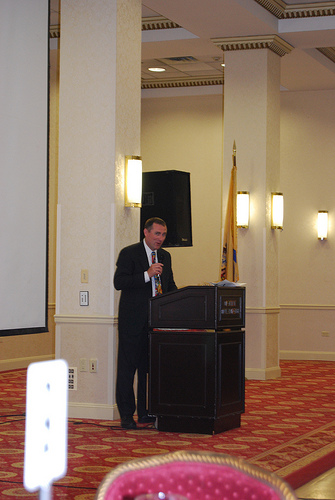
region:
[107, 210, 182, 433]
man wearing black suit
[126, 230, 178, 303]
man wearing white shirt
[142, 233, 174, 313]
man wearing floral tie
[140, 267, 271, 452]
black stand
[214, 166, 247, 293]
yellow flag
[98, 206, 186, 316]
man holding mike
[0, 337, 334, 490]
red carpet on ground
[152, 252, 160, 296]
The tie the man is wearing.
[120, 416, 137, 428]
The left black shoe the man is wearing.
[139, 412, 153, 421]
The right black shoe the man is wearing.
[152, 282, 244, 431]
The podium in front of the man.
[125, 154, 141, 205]
The lamp mounted on the wall behind the man.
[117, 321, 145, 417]
The black pants the man is wearing.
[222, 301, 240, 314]
The engraved letters on the front of the podium.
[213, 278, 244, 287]
The white paper on the podium.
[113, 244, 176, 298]
The black suit jacket the man is wearing.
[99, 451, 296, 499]
The top of the chair.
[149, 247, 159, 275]
a man wearing a tie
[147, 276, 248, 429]
a wood podium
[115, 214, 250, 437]
a man standing at a podium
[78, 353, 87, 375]
a white electrical outlet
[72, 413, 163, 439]
a black cord on a the floor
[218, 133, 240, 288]
a flag and flag pole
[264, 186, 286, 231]
a light mounted to the wall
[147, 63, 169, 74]
a light mounted into the cieling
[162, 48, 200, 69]
a heating and air vent in the cieling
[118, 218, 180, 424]
man standing at lecturn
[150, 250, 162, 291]
necktie man is wearing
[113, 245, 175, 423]
black suit man is wearing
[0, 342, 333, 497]
red and gold carpeting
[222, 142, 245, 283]
flag on flag stand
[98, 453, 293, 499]
gold and red chair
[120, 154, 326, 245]
light fixtures on wall and pillars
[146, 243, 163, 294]
white dress shirt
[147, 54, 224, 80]
lights recessed in ceiling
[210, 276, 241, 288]
papers on the lecturn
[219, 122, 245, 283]
the yellow flag behind the podium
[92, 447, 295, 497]
thr red patterned chair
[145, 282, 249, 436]
the solid black podium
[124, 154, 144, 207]
the wall light above the man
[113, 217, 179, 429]
the man is speaking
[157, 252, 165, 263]
the microphone is black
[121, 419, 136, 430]
the black shiny shoes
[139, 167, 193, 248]
the black object behind the man's head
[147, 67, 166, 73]
the light in the ceiling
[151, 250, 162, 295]
the man's colorful tie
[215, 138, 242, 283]
A yellow colored flag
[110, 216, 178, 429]
A man wearing a suit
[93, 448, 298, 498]
Top of a red chair